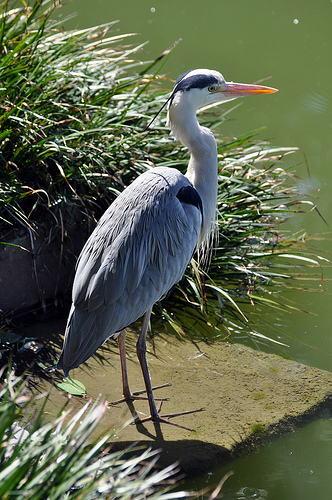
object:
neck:
[170, 115, 219, 208]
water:
[237, 13, 306, 66]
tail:
[57, 310, 98, 375]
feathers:
[69, 167, 190, 311]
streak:
[176, 184, 203, 228]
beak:
[223, 82, 278, 97]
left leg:
[118, 331, 130, 399]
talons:
[136, 398, 206, 433]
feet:
[135, 399, 205, 432]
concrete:
[34, 327, 322, 447]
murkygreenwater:
[215, 414, 327, 496]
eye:
[208, 85, 216, 93]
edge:
[236, 416, 289, 446]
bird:
[56, 66, 278, 431]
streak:
[169, 74, 215, 109]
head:
[171, 68, 278, 110]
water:
[141, 403, 319, 497]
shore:
[0, 329, 332, 485]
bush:
[0, 10, 318, 325]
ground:
[235, 372, 269, 399]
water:
[229, 302, 314, 363]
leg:
[135, 318, 156, 420]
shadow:
[120, 436, 240, 472]